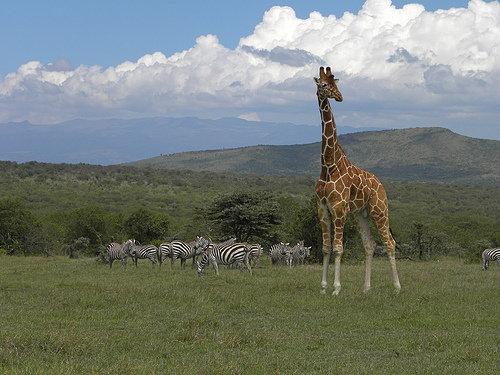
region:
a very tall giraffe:
[297, 41, 401, 324]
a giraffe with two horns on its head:
[305, 59, 350, 108]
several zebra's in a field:
[53, 224, 319, 310]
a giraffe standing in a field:
[248, 36, 430, 312]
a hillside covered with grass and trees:
[82, 111, 474, 207]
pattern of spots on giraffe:
[305, 177, 377, 219]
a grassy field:
[1, 295, 446, 369]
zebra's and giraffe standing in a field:
[53, 84, 410, 309]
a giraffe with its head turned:
[287, 41, 367, 159]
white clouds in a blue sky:
[1, 24, 260, 141]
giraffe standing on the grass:
[298, 63, 426, 308]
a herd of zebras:
[87, 223, 319, 283]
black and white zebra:
[478, 244, 499, 271]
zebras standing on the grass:
[89, 224, 316, 279]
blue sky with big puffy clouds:
[1, 3, 499, 161]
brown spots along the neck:
[317, 102, 343, 159]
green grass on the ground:
[2, 251, 499, 374]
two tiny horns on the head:
[318, 61, 332, 78]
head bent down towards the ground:
[191, 254, 210, 274]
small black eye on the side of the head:
[321, 81, 332, 89]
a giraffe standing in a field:
[311, 61, 402, 301]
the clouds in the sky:
[135, 42, 182, 114]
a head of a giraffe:
[310, 65, 342, 105]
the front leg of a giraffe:
[327, 210, 347, 295]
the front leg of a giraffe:
[315, 202, 330, 297]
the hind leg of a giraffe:
[377, 197, 398, 292]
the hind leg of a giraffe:
[355, 216, 375, 291]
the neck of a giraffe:
[318, 101, 335, 153]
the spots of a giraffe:
[337, 165, 359, 189]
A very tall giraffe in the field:
[307, 63, 421, 294]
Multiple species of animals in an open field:
[67, 62, 494, 325]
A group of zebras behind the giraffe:
[100, 228, 315, 280]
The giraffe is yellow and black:
[292, 74, 418, 305]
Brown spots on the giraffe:
[307, 158, 416, 268]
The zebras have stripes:
[91, 232, 252, 273]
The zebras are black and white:
[105, 228, 311, 283]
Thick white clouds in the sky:
[22, 8, 490, 108]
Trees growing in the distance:
[27, 196, 281, 268]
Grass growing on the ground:
[168, 319, 422, 364]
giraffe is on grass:
[280, 61, 452, 333]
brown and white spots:
[312, 88, 449, 306]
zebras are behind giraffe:
[98, 220, 338, 282]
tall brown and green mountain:
[35, 117, 483, 243]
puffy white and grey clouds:
[102, 4, 480, 110]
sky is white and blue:
[12, 21, 278, 101]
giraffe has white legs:
[314, 217, 420, 327]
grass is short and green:
[54, 278, 275, 343]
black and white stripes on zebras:
[108, 224, 284, 281]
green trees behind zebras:
[51, 195, 426, 267]